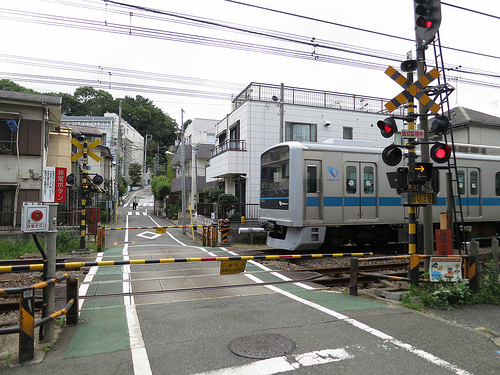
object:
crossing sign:
[382, 64, 439, 112]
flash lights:
[430, 141, 451, 163]